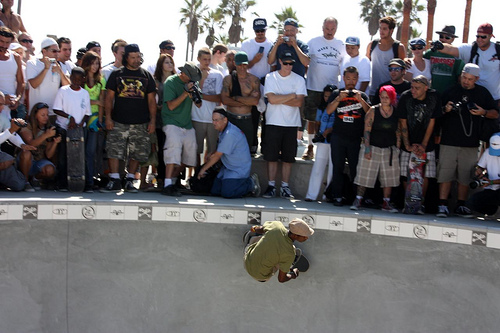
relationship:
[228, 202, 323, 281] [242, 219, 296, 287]
skater in shirt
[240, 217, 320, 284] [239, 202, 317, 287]
man watching skater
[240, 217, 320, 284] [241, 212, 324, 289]
man watching skater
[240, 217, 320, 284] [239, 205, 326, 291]
man watching skater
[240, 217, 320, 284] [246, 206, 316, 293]
man watching skater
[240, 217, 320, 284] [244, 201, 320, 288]
man watching skater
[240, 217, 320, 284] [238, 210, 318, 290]
man watching skater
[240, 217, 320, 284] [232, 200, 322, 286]
man watching skater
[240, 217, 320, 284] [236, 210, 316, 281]
man watching skater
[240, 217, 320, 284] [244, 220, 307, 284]
man on skateboard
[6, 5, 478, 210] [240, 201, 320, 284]
people watching man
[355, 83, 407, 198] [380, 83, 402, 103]
girl with hair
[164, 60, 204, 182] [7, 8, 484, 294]
man taking picture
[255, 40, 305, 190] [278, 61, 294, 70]
man with sunglasses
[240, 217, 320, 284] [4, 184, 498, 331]
man in skate bowl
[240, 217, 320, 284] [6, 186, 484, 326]
man in skatebowl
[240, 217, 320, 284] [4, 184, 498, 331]
man in a skate bowl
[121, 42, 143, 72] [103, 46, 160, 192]
head of a person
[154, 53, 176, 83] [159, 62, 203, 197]
head of a man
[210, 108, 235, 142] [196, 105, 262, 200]
head of a man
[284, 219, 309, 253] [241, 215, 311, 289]
head of a person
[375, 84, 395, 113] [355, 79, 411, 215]
head of a person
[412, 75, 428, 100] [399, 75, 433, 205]
head of a person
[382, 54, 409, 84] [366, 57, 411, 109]
head of a person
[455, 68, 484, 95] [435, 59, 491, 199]
head of a person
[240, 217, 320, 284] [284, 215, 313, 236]
man wearing a hat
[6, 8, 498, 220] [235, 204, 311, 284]
audience watching skateboarder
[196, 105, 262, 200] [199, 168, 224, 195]
man on knees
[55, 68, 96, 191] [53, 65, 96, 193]
man holding man